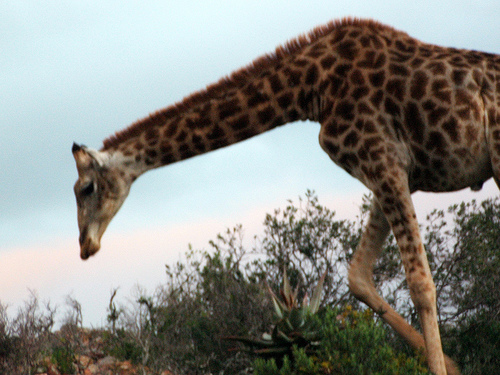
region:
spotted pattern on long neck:
[135, 87, 302, 161]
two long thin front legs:
[345, 177, 453, 371]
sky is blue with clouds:
[169, 164, 264, 226]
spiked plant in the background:
[221, 266, 323, 353]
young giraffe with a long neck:
[70, 17, 497, 369]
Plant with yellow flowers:
[327, 301, 381, 372]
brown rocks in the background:
[70, 329, 145, 371]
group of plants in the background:
[169, 222, 494, 372]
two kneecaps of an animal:
[344, 257, 451, 324]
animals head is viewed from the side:
[53, 127, 134, 266]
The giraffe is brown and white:
[56, 29, 487, 354]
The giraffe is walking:
[63, 34, 470, 342]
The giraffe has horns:
[68, 126, 116, 174]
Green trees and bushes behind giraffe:
[0, 168, 472, 357]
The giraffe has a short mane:
[86, 13, 363, 210]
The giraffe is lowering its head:
[47, 11, 424, 305]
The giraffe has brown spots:
[61, 25, 488, 325]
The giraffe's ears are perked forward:
[38, 121, 135, 265]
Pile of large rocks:
[18, 310, 167, 370]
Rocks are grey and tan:
[23, 318, 148, 364]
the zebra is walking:
[59, 26, 484, 262]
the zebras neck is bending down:
[32, 55, 355, 283]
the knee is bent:
[293, 202, 410, 335]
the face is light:
[40, 131, 135, 265]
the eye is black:
[59, 176, 111, 208]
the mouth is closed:
[52, 209, 106, 269]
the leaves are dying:
[118, 211, 338, 363]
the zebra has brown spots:
[161, 47, 466, 174]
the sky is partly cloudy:
[13, 15, 215, 271]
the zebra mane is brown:
[102, 22, 357, 167]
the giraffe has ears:
[18, 85, 159, 277]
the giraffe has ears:
[54, 104, 197, 360]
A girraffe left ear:
[63, 133, 93, 174]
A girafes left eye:
[71, 171, 101, 191]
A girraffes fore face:
[65, 212, 115, 262]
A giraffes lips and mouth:
[80, 240, 100, 265]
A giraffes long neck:
[101, 13, 411, 178]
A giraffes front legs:
[310, 121, 445, 370]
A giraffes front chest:
[297, 95, 353, 170]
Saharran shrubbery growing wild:
[195, 202, 321, 330]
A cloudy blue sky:
[27, 52, 78, 102]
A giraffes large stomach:
[411, 68, 487, 198]